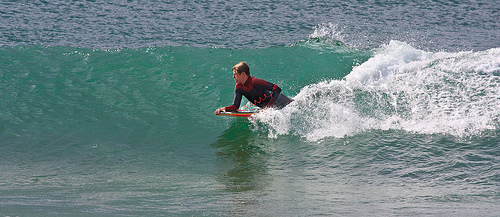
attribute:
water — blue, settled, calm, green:
[1, 1, 499, 216]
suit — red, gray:
[224, 77, 294, 110]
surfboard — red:
[217, 108, 267, 116]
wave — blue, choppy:
[2, 44, 379, 130]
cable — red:
[242, 91, 274, 111]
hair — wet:
[233, 62, 251, 77]